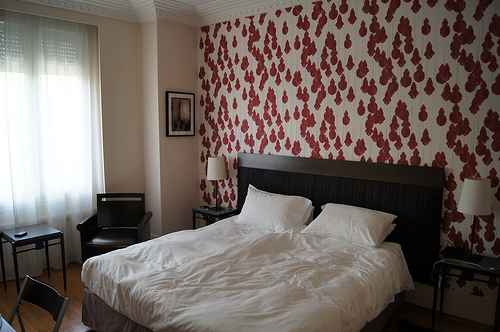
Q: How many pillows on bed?
A: Two.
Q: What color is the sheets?
A: White.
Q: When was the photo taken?
A: Daytime.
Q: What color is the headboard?
A: Black.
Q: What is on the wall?
A: A painting.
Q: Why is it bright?
A: Sunny.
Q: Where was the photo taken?
A: In a bedroom.